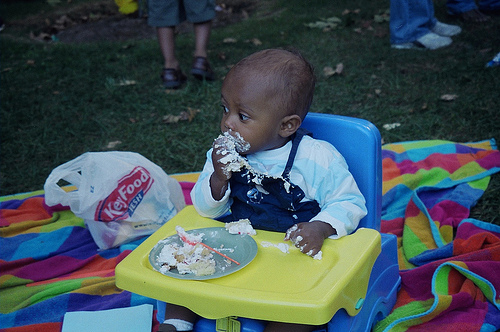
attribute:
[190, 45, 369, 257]
baby — sitting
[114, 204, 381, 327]
tray — yellow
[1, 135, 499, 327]
beach blanket — colorful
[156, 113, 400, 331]
chair — blue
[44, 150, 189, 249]
bag — plastic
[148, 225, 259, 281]
plate — gray